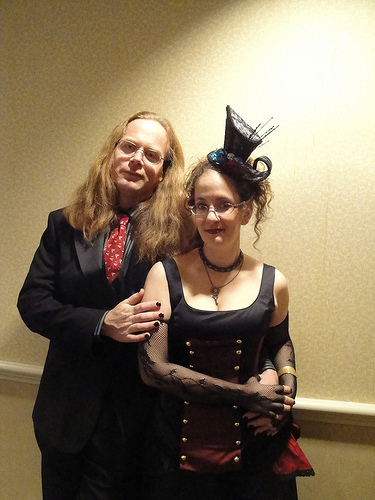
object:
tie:
[102, 212, 133, 284]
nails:
[156, 301, 161, 306]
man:
[17, 111, 203, 500]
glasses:
[115, 139, 169, 164]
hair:
[64, 110, 196, 263]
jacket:
[16, 203, 163, 455]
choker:
[199, 243, 244, 273]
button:
[236, 339, 242, 344]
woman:
[137, 149, 314, 498]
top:
[145, 256, 316, 480]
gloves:
[137, 321, 285, 419]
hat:
[206, 103, 279, 201]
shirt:
[104, 208, 138, 303]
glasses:
[188, 196, 253, 216]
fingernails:
[158, 313, 164, 319]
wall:
[2, 2, 372, 498]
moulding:
[3, 360, 375, 437]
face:
[195, 172, 238, 247]